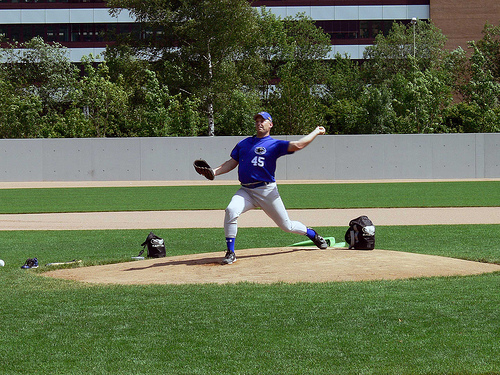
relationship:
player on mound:
[194, 112, 327, 267] [38, 245, 497, 285]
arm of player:
[277, 125, 326, 158] [194, 112, 327, 267]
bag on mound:
[345, 215, 376, 250] [38, 245, 497, 285]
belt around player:
[241, 183, 275, 188] [194, 112, 327, 267]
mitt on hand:
[194, 160, 213, 180] [195, 161, 215, 178]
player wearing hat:
[194, 112, 327, 267] [254, 112, 272, 121]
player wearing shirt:
[194, 112, 327, 267] [230, 136, 292, 185]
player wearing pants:
[194, 112, 327, 267] [224, 181, 306, 239]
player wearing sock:
[194, 112, 327, 267] [227, 237, 235, 251]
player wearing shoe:
[194, 112, 327, 267] [222, 252, 236, 264]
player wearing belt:
[194, 112, 327, 267] [241, 183, 275, 188]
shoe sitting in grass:
[22, 258, 38, 271] [0, 222, 498, 373]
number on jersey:
[252, 156, 265, 167] [230, 136, 292, 185]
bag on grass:
[139, 231, 166, 258] [0, 222, 498, 373]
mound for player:
[38, 245, 497, 285] [194, 112, 327, 267]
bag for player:
[345, 215, 376, 250] [194, 112, 327, 267]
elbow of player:
[297, 138, 307, 148] [194, 112, 327, 267]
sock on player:
[227, 237, 235, 251] [194, 112, 327, 267]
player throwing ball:
[194, 112, 327, 267] [318, 125, 326, 131]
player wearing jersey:
[194, 112, 327, 267] [230, 136, 292, 185]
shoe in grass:
[22, 258, 38, 271] [0, 222, 498, 373]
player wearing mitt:
[194, 112, 327, 267] [194, 160, 213, 180]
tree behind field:
[274, 7, 333, 133] [0, 132, 499, 374]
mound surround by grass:
[38, 245, 497, 285] [0, 222, 498, 373]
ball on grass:
[0, 258, 4, 269] [0, 222, 498, 373]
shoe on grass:
[22, 258, 38, 271] [0, 222, 498, 373]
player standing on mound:
[194, 112, 327, 267] [38, 245, 497, 285]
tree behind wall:
[274, 7, 333, 133] [273, 131, 498, 183]